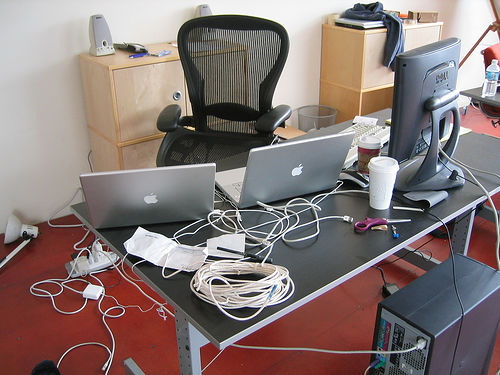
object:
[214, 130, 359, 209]
laptop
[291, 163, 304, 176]
logo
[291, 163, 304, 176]
bitten apple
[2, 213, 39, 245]
lamp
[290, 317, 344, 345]
floor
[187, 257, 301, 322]
cord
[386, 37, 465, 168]
computer monitor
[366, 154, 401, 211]
coffee cup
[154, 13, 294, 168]
chair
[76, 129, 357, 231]
two laptops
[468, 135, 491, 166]
desk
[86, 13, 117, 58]
speakers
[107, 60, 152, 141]
cubicle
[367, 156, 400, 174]
lid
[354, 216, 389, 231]
handle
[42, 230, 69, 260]
table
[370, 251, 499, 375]
computer box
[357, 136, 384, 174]
coffee cup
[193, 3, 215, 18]
speaker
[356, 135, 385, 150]
top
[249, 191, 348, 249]
cords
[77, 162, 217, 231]
laptops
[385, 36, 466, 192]
desk computers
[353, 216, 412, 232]
scissors